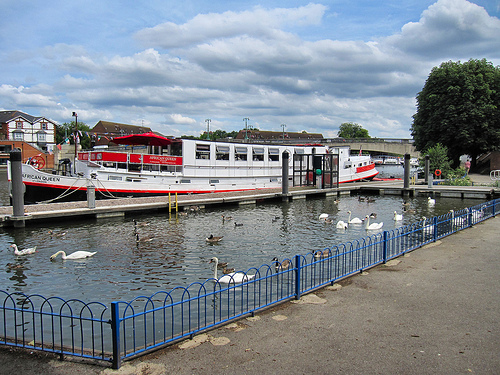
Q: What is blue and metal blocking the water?
A: A fence.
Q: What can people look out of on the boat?
A: Windows.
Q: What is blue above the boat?
A: The sky.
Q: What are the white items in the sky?
A: Clouds.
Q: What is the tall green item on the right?
A: A tree.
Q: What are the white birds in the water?
A: Swans.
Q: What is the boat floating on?
A: Water.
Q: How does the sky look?
A: Very cloudy.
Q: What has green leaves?
A: Big tree.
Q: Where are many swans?
A: In the water.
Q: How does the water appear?
A: Calm.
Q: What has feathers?
A: Swans.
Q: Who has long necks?
A: The swans.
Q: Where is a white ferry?
A: On the water.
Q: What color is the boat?
A: White.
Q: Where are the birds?
A: The water.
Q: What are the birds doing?
A: Wading.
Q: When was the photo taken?
A: Day time.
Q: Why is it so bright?
A: Sunny.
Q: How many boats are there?
A: One.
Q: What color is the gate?
A: Blue.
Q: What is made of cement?
A: The sidewalk.